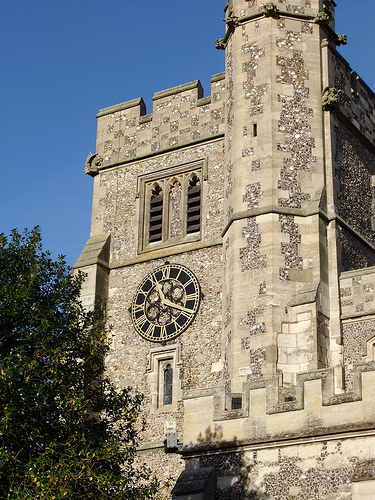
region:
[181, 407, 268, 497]
Shade spot on a building.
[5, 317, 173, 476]
Tall green tree by building.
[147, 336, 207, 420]
Decorative window on a building.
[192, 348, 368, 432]
A stone balcony on building.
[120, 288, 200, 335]
A black and gold clock.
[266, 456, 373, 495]
Rocks on side of building.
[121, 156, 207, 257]
Two air vents on building.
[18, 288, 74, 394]
Blue sky through green trees.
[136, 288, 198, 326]
Black circles in middle of clock.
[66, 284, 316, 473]
Building with a clock face on it.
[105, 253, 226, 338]
clock on front of building over narrow window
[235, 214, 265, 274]
panels of rocks mixed with solid blocks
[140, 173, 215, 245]
louvered panels slanted downwards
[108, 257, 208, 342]
circles within black ring of clock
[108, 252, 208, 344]
gold hands indicating it is late morning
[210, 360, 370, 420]
angular cutouts making a repeated pattern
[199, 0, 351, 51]
protruding figures around edge of tower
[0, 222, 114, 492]
tall tree covering edge of building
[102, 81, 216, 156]
checkerboard-type pattern at top of building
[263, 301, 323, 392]
stone-block surface revealed underneath facade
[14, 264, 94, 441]
this is a tree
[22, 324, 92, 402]
the tree has green leaves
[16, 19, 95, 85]
this is the sky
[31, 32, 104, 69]
the sky is blue in color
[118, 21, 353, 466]
this is a building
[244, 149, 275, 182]
this is the wall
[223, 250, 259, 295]
the wall is made with stones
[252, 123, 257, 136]
this is an opening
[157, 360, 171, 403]
this is a window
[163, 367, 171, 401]
thew window is closed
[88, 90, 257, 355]
the building is a clock tower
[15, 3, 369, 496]
the building is constructed of stone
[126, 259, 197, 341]
the clock face is black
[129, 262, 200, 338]
the hands of the clock are beige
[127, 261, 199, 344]
the Roman numerals are beige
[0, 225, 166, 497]
a green tree is next to the tower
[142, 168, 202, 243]
the windows are arched and recessed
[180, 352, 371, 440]
a balcony is midway up the castle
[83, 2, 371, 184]
parapets are on the top of the castle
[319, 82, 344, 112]
gargoyles are on the sides of the castle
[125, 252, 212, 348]
An old fashioned clock on a building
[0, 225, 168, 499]
A tall green tree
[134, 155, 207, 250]
A window on the stone building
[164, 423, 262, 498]
The tree's shadow on the building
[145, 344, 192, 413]
A thin window with glass pane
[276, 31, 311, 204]
A mosaic type of decoration on the building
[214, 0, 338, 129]
The tower top of the building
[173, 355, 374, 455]
A balcony wall with square shapes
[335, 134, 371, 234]
A wall covered with stones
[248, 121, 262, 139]
A tiny black hole in the tower